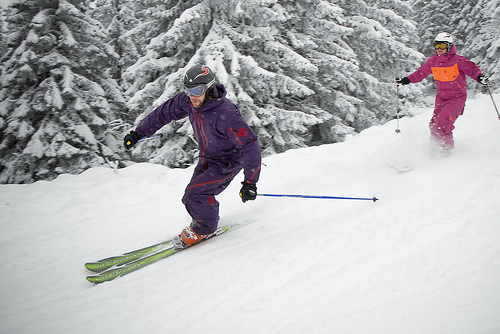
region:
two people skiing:
[77, 19, 497, 316]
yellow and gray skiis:
[73, 242, 163, 299]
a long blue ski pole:
[249, 185, 410, 217]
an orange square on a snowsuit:
[424, 60, 470, 85]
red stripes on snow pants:
[184, 175, 229, 190]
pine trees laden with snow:
[259, 8, 357, 124]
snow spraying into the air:
[407, 133, 447, 161]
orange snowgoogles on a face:
[428, 40, 446, 51]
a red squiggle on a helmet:
[194, 64, 211, 79]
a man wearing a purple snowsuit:
[132, 52, 274, 247]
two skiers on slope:
[114, 23, 479, 271]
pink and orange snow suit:
[409, 49, 477, 148]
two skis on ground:
[73, 233, 176, 300]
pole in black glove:
[235, 183, 380, 208]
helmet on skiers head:
[181, 56, 218, 96]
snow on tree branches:
[259, 20, 334, 120]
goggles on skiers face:
[179, 81, 211, 104]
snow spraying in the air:
[382, 120, 449, 184]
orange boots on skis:
[172, 225, 210, 251]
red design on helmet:
[195, 65, 215, 85]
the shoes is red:
[159, 208, 240, 265]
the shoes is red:
[157, 185, 307, 325]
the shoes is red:
[175, 188, 237, 240]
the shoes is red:
[165, 221, 265, 308]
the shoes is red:
[199, 198, 283, 303]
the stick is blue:
[229, 178, 399, 245]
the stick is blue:
[239, 180, 480, 312]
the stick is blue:
[252, 178, 372, 216]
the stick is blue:
[249, 157, 386, 228]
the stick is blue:
[226, 128, 397, 199]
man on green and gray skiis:
[67, 37, 335, 324]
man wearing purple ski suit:
[42, 47, 291, 291]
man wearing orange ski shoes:
[72, 18, 296, 300]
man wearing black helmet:
[64, 42, 342, 307]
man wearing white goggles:
[70, 35, 285, 265]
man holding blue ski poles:
[68, 32, 383, 284]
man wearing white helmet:
[379, 12, 479, 172]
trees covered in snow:
[15, 7, 436, 140]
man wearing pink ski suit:
[387, 10, 474, 164]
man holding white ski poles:
[370, 22, 492, 171]